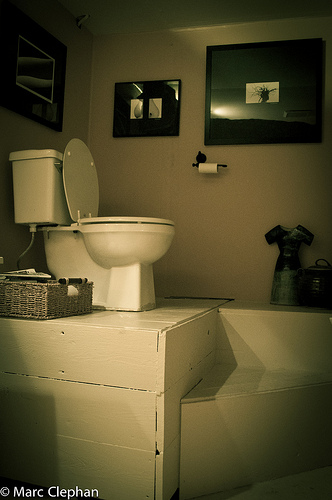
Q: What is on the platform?
A: Toilet.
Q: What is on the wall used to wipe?
A: Toilet paper.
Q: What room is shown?
A: Bathroom.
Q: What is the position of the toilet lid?
A: Raised.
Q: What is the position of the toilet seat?
A: Down.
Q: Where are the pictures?
A: Hanging on the wall.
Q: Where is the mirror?
A: On the wall behind the toilet.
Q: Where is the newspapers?
A: In the basket.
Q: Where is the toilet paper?
A: Hanging on the wall.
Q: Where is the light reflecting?
A: On the pictures.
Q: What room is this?
A: A bathroom.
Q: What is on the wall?
A: A television.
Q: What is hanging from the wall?
A: Toilet paper.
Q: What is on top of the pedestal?
A: A toilet.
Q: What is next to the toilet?
A: A square basket.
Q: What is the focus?
A: Toilet.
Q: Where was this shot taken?
A: Bathroom.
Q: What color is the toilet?
A: White.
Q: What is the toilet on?
A: Platform.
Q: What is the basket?
A: Magazines.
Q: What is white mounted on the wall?
A: Toilet paper.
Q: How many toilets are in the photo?
A: 1.